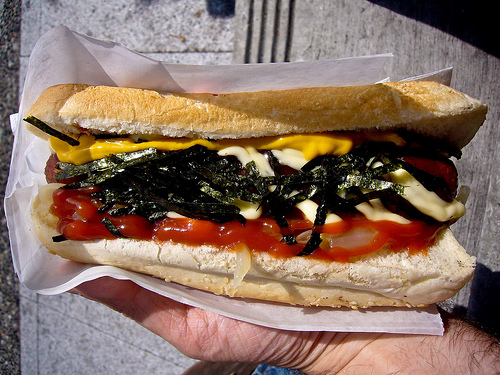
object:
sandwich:
[22, 78, 491, 312]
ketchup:
[49, 187, 442, 260]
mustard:
[48, 130, 354, 165]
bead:
[221, 145, 305, 174]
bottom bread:
[30, 180, 479, 311]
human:
[65, 275, 500, 375]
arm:
[340, 320, 498, 375]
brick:
[21, 0, 244, 54]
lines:
[244, 0, 256, 63]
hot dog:
[358, 144, 461, 219]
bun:
[28, 81, 494, 149]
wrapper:
[0, 22, 456, 338]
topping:
[241, 170, 465, 229]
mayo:
[352, 174, 407, 201]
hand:
[55, 261, 349, 367]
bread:
[20, 78, 493, 312]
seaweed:
[20, 114, 417, 258]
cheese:
[219, 145, 304, 174]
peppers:
[124, 223, 139, 233]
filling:
[16, 112, 475, 261]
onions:
[238, 252, 247, 262]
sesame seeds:
[316, 297, 326, 303]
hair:
[427, 306, 499, 375]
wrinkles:
[208, 320, 279, 362]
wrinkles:
[283, 336, 298, 347]